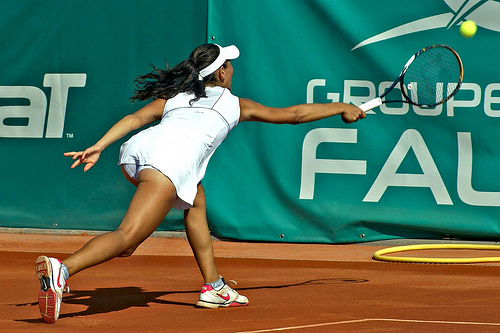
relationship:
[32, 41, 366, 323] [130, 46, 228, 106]
player hair do pony tail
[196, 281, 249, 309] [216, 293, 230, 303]
shoe has symbol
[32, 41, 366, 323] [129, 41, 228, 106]
player has hair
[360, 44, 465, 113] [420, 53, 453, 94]
racket has letter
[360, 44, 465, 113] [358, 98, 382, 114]
racket has handle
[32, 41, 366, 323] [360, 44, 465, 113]
player has racket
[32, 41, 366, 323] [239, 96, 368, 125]
player has arm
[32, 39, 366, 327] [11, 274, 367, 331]
player casting shadow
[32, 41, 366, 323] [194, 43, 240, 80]
player wearing visor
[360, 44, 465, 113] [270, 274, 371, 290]
racket casting shadow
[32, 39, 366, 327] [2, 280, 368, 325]
player casting shadow